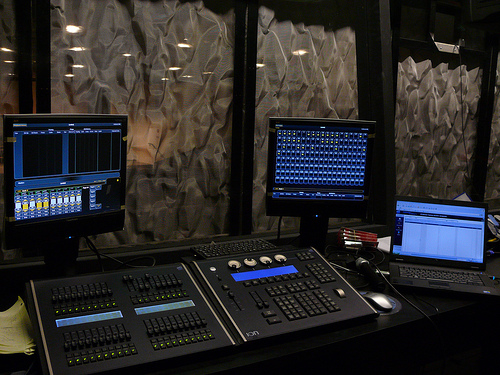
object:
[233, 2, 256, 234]
jamb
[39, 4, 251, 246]
window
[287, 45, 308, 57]
lights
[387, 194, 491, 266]
monitor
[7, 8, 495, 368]
control room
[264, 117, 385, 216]
screen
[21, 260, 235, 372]
board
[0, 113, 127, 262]
monitor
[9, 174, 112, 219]
icons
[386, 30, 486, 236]
window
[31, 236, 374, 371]
mixer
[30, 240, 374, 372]
counter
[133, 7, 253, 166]
reflecting window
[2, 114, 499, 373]
booth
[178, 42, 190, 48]
reflection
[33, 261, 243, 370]
monitor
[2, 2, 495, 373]
sound room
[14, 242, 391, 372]
equipment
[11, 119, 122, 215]
screen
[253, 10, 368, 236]
window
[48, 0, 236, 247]
material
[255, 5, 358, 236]
material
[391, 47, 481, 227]
material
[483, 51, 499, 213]
material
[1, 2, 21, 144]
material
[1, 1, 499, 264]
wall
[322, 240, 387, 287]
microphone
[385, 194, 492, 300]
laptop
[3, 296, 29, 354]
papers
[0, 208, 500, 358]
desk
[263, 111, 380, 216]
monitor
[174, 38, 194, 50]
light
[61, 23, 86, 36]
light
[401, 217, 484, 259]
file list